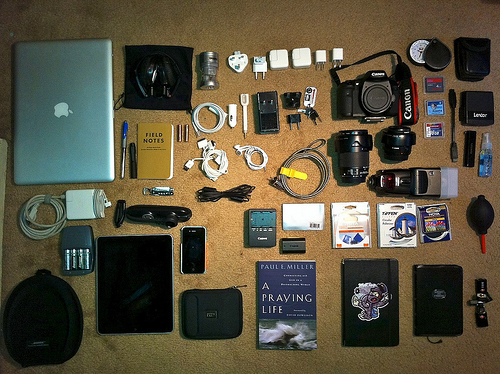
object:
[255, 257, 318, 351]
book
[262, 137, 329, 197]
wiring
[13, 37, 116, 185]
computer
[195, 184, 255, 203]
cord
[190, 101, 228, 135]
cord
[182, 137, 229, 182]
cord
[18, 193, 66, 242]
cord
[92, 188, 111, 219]
cord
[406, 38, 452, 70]
compass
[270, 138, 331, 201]
grey cord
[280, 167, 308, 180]
yellow tie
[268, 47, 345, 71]
blocks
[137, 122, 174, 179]
notebook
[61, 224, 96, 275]
charger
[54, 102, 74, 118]
logo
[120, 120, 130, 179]
pen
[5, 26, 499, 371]
electronics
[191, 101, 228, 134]
cords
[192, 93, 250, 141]
wire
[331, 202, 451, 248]
packages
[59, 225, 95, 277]
container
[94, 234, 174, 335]
tablet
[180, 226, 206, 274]
cell phone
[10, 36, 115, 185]
laptop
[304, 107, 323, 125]
keys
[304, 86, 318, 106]
key chain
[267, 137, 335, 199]
cord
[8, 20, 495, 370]
rug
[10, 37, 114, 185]
apple laptop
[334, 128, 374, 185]
lens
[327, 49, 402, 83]
strap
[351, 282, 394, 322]
sticker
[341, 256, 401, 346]
wallet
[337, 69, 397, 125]
camera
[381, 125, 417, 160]
lens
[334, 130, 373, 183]
camera lens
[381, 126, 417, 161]
camera lens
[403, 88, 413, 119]
lettering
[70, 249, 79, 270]
battery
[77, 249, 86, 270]
battery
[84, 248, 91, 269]
battery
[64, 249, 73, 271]
battery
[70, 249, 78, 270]
battery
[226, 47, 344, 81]
electrical adapters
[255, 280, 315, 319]
title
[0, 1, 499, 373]
surface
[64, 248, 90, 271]
batteries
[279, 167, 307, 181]
strap